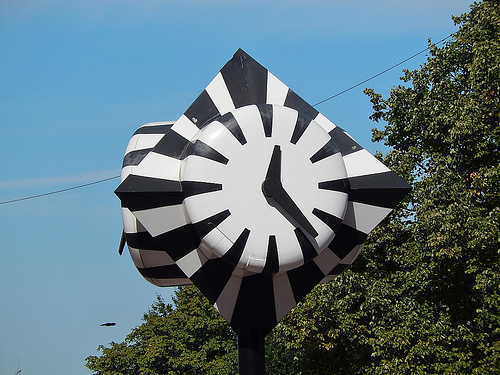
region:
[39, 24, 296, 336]
picture taken during the day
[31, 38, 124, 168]
the sky is clear of clouds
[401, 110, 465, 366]
green trees on the right side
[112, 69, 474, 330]
a modern clock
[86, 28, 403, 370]
the clock is black and white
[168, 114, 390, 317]
the clock shows 12:24 pm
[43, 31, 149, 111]
no clouds in the sky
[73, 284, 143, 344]
a bird is mid flight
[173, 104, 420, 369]
no numbers on the clock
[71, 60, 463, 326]
the clock has stripes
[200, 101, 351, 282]
clock face on a pole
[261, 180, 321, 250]
minute hand of the clock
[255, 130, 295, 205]
hour hand of the clock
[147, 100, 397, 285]
clock face on the pole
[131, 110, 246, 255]
zebra sripes on the clock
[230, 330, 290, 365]
black pole holding the clock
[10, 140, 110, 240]
telephone line against the sky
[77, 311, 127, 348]
bird flying in the sky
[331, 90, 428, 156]
tree branches against sky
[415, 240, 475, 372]
black hole in tree branches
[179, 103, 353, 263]
a modern looking clock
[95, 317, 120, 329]
a bird flying through the air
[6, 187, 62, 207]
high-voltage power lines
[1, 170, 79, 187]
contrails from a jet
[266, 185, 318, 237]
the minute hand from a clock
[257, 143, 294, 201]
the hour hand on a clock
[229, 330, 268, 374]
support post four a clock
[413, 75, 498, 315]
leaves of a tree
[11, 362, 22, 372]
the top part of the streetlight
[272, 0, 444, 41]
thin clouds in the sky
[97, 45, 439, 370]
a tall outside clock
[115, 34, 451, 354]
a black and white clock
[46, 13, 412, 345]
a black and white clock with black arms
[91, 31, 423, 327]
the arms of the clock are black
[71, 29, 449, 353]
a black and white clock outside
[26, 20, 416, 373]
a black and white outside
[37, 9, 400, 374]
a black and white clock outside on a pole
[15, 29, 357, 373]
a pole with a clock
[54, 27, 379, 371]
a pole with a black and white clock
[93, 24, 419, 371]
a pole with an outside clock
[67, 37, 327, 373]
a clock that is outside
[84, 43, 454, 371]
a clock outside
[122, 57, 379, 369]
a clock on a pole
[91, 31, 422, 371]
a black and white clcok on pole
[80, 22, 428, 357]
an outside clock that is tall